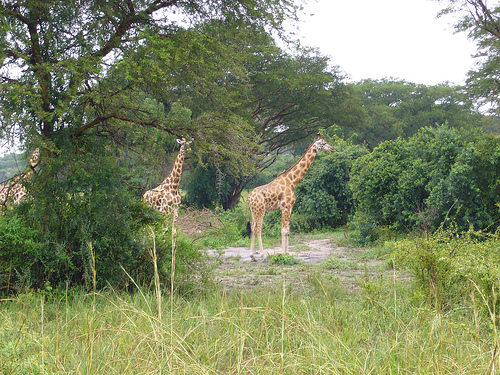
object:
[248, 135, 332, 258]
girafee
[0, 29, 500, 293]
forrest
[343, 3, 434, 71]
sky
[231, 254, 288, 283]
ground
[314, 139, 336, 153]
head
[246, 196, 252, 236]
tail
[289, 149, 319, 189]
neck